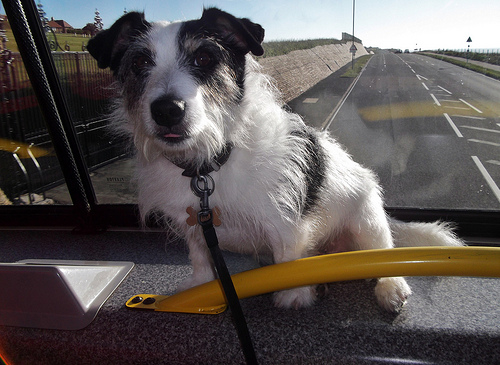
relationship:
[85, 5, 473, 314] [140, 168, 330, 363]
dog wearing leash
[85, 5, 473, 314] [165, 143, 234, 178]
dog wearing collar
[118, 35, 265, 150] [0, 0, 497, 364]
dog in car